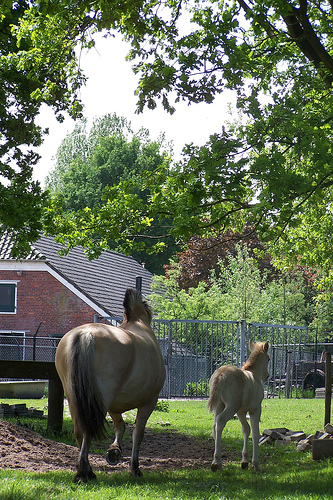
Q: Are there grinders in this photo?
A: No, there are no grinders.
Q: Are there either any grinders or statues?
A: No, there are no grinders or statues.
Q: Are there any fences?
A: Yes, there is a fence.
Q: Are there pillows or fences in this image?
A: Yes, there is a fence.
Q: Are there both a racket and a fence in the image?
A: No, there is a fence but no rackets.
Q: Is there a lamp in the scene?
A: No, there are no lamps.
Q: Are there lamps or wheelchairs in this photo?
A: No, there are no lamps or wheelchairs.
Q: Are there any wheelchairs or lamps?
A: No, there are no lamps or wheelchairs.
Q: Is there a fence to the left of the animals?
A: Yes, there is a fence to the left of the animals.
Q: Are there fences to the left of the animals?
A: Yes, there is a fence to the left of the animals.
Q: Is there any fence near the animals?
A: Yes, there is a fence near the animals.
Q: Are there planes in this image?
A: No, there are no planes.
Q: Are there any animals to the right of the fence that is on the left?
A: Yes, there are animals to the right of the fence.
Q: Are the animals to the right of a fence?
A: Yes, the animals are to the right of a fence.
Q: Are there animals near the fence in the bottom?
A: Yes, there are animals near the fence.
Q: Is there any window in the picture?
A: Yes, there is a window.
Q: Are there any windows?
A: Yes, there is a window.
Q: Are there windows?
A: Yes, there is a window.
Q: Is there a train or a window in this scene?
A: Yes, there is a window.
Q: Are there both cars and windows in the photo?
A: No, there is a window but no cars.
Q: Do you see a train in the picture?
A: No, there are no trains.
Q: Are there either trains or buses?
A: No, there are no trains or buses.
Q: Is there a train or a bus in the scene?
A: No, there are no trains or buses.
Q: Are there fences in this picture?
A: Yes, there is a fence.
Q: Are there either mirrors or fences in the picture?
A: Yes, there is a fence.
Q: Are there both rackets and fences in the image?
A: No, there is a fence but no rackets.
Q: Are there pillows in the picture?
A: No, there are no pillows.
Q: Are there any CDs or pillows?
A: No, there are no pillows or cds.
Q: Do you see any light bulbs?
A: No, there are no light bulbs.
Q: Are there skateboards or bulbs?
A: No, there are no bulbs or skateboards.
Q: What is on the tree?
A: The leaves are on the tree.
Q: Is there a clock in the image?
A: No, there are no clocks.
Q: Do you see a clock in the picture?
A: No, there are no clocks.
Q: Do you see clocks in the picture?
A: No, there are no clocks.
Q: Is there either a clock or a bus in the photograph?
A: No, there are no clocks or buses.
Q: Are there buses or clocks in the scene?
A: No, there are no clocks or buses.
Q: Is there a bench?
A: No, there are no benches.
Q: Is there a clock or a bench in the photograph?
A: No, there are no benches or clocks.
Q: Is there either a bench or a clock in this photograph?
A: No, there are no benches or clocks.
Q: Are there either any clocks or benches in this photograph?
A: No, there are no benches or clocks.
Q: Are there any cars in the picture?
A: No, there are no cars.